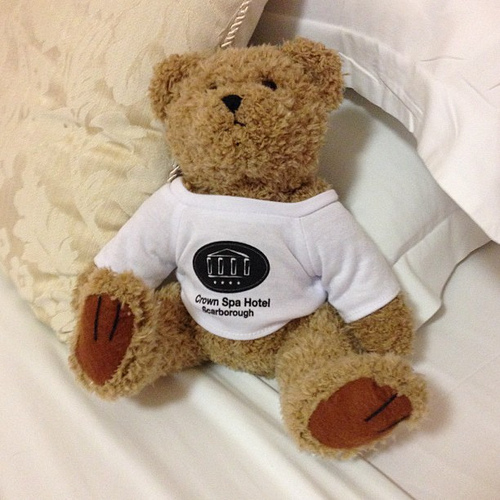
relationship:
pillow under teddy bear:
[318, 88, 493, 333] [68, 35, 428, 460]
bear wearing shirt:
[76, 29, 450, 460] [91, 177, 399, 341]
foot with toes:
[61, 274, 158, 396] [71, 292, 135, 342]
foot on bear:
[61, 274, 158, 396] [76, 29, 450, 460]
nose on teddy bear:
[220, 93, 242, 110] [68, 35, 428, 460]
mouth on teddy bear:
[222, 119, 247, 131] [68, 35, 428, 460]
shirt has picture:
[91, 177, 399, 341] [187, 235, 272, 292]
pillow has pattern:
[31, 56, 106, 216] [32, 86, 98, 226]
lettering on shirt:
[195, 293, 272, 321] [146, 214, 325, 340]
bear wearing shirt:
[76, 29, 450, 460] [96, 181, 404, 341]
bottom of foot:
[73, 291, 137, 387] [64, 266, 159, 406]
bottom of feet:
[305, 374, 412, 452] [292, 357, 426, 465]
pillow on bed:
[318, 88, 491, 334] [0, 381, 498, 498]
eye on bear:
[201, 78, 220, 93] [76, 29, 450, 460]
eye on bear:
[255, 77, 282, 92] [76, 29, 450, 460]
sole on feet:
[306, 379, 407, 442] [292, 357, 426, 465]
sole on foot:
[78, 289, 134, 379] [61, 274, 158, 396]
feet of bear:
[292, 357, 426, 465] [76, 29, 450, 460]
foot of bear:
[61, 274, 158, 396] [76, 29, 450, 460]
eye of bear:
[205, 81, 218, 92] [76, 29, 450, 460]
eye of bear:
[259, 78, 277, 92] [76, 29, 450, 460]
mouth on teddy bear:
[222, 119, 248, 133] [121, 30, 416, 373]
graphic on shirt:
[184, 236, 274, 321] [89, 172, 404, 346]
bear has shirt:
[69, 36, 428, 462] [89, 172, 404, 346]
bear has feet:
[76, 29, 450, 460] [292, 357, 426, 465]